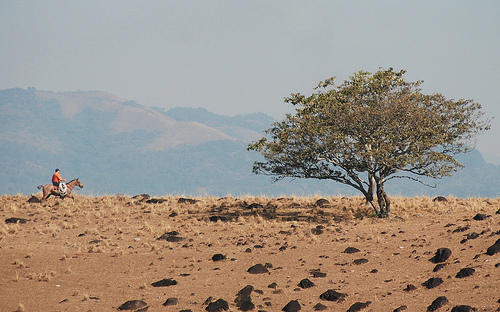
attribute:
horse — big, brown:
[37, 178, 84, 201]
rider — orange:
[51, 169, 66, 192]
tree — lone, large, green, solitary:
[246, 67, 495, 219]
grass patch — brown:
[65, 264, 74, 274]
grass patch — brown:
[83, 294, 89, 302]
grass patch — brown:
[16, 303, 25, 312]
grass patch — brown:
[13, 258, 21, 265]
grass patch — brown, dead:
[38, 270, 50, 282]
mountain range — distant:
[0, 87, 499, 199]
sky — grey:
[1, 0, 500, 166]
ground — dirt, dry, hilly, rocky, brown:
[0, 196, 499, 312]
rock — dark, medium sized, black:
[281, 301, 301, 312]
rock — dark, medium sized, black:
[297, 278, 316, 289]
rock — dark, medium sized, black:
[319, 289, 345, 301]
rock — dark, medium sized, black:
[347, 301, 372, 312]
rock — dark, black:
[313, 303, 328, 312]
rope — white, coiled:
[59, 182, 68, 195]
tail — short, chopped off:
[37, 184, 44, 190]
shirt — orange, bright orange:
[52, 172, 61, 182]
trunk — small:
[360, 187, 380, 215]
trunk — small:
[376, 185, 387, 214]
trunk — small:
[381, 187, 390, 212]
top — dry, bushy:
[246, 67, 495, 189]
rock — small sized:
[387, 292, 392, 296]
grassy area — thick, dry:
[0, 192, 500, 227]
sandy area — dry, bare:
[0, 213, 500, 311]